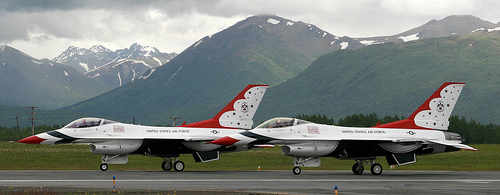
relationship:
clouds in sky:
[0, 0, 500, 60] [1, 2, 498, 38]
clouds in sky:
[0, 0, 500, 60] [99, 7, 221, 59]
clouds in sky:
[0, 0, 500, 60] [71, 24, 190, 72]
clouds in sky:
[0, 0, 500, 60] [117, 15, 199, 51]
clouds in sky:
[0, 0, 500, 60] [4, 3, 484, 62]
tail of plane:
[184, 81, 270, 129] [8, 81, 273, 173]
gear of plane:
[338, 157, 389, 182] [237, 78, 487, 193]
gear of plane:
[96, 158, 118, 178] [11, 84, 267, 179]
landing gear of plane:
[346, 156, 386, 177] [209, 75, 481, 175]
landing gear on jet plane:
[170, 157, 185, 175] [26, 84, 274, 164]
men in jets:
[33, 99, 251, 163] [15, 80, 474, 177]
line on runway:
[0, 178, 500, 182] [8, 152, 499, 193]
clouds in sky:
[0, 0, 500, 60] [139, 6, 194, 41]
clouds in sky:
[62, 3, 193, 81] [0, 4, 415, 64]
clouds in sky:
[0, 0, 500, 60] [2, 13, 390, 47]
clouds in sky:
[0, 0, 500, 60] [0, 0, 497, 128]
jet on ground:
[15, 84, 270, 172] [2, 162, 484, 192]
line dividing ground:
[2, 174, 484, 184] [0, 169, 500, 193]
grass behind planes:
[7, 137, 499, 175] [12, 79, 484, 181]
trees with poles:
[12, 107, 499, 152] [9, 107, 44, 143]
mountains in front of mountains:
[256, 32, 499, 132] [65, 15, 315, 137]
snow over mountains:
[392, 31, 424, 40] [2, 13, 499, 123]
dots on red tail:
[222, 108, 261, 128] [181, 72, 278, 142]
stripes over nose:
[16, 131, 76, 146] [9, 122, 66, 149]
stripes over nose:
[206, 129, 272, 146] [9, 122, 66, 149]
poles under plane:
[5, 102, 37, 134] [8, 81, 273, 173]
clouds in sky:
[0, 0, 500, 60] [11, 7, 168, 56]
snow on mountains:
[265, 15, 280, 27] [2, 15, 499, 134]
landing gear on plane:
[288, 154, 321, 167] [209, 75, 481, 175]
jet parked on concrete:
[210, 78, 475, 176] [0, 168, 498, 193]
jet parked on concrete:
[11, 81, 269, 169] [0, 168, 498, 193]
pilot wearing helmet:
[274, 119, 285, 130] [273, 115, 283, 125]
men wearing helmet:
[70, 120, 102, 128] [79, 117, 88, 124]